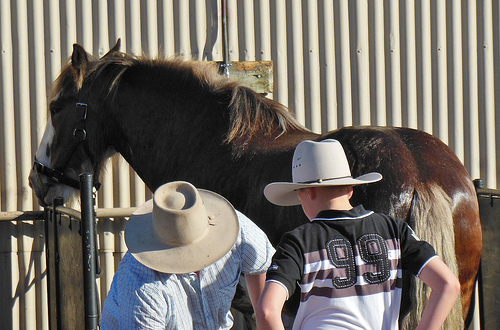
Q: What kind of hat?
A: Cowboy.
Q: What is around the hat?
A: Rope.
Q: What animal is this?
A: Horse.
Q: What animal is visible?
A: A horse.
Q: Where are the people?
A: In front of the horse.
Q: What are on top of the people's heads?
A: Hats.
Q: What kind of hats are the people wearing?
A: Cowboy hats.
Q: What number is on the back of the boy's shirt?
A: 99.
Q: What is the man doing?
A: Bending down.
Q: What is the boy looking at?
A: The man.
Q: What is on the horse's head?
A: A harness.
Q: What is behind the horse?
A: A building.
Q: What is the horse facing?
A: A building.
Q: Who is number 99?
A: The boy.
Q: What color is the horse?
A: Brown.